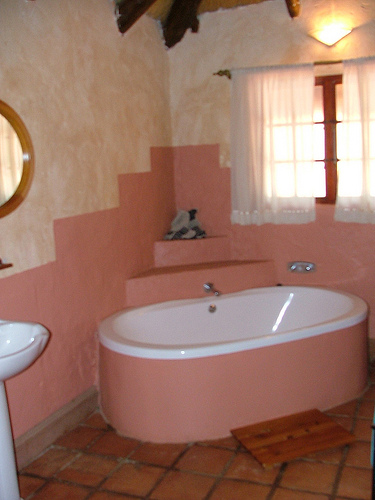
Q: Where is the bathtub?
A: In the corner of the bathroom.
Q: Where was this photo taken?
A: In a bathroom.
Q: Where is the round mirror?
A: Above the sink.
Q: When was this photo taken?
A: During daylight.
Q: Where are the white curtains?
A: On the window above the tub.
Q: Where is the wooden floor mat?
A: In front of the bathtub.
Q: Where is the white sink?
A: Under the mirror.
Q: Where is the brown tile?
A: On the bathroom floor.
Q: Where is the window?
A: Above the bathtub.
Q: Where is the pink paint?
A: Around the bathtub.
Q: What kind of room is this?
A: Bathroom.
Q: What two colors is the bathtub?
A: Pink and white.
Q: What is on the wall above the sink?
A: A mirror.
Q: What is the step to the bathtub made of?
A: Wood.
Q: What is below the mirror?
A: Sink.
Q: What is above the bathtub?
A: Windows.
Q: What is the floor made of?
A: Tiles.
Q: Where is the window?
A: Above the bathtub.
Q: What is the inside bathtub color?
A: White.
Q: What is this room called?
A: Bathroom.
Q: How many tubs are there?
A: 1.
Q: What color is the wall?
A: Pink and beige.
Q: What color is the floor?
A: Brown.